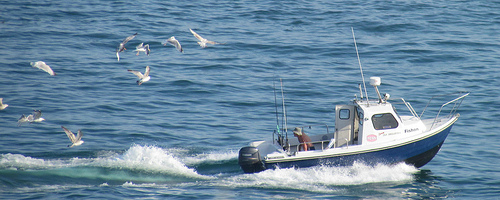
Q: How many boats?
A: One.